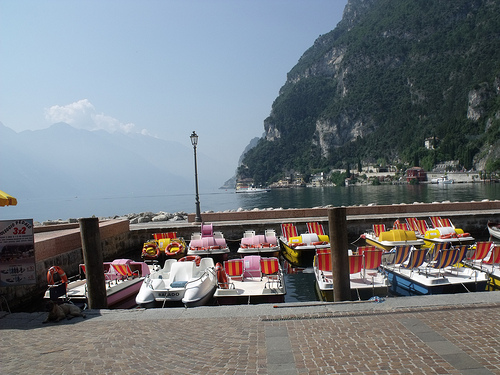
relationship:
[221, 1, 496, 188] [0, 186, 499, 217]
mountain in front ocean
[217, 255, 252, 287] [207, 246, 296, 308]
chair sitting on boat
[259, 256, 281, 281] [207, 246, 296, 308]
chairs sitting on boat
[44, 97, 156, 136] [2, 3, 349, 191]
cloud in sky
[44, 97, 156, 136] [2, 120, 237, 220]
cloud over mountain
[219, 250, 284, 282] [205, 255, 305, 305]
chairs on a boat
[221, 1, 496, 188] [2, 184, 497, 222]
mountain behind water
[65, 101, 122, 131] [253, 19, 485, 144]
cloud behind mountain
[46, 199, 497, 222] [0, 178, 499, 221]
rocks in front of water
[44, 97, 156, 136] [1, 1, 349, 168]
cloud in sky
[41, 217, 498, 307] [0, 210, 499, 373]
boats at dock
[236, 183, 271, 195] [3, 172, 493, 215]
boat in water